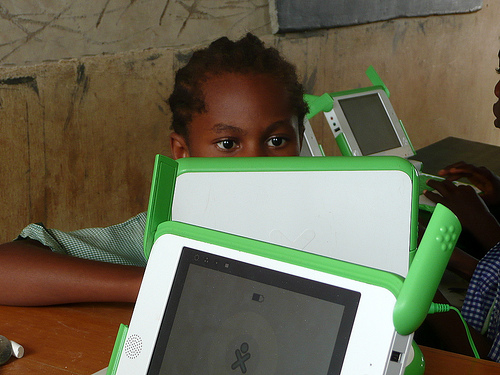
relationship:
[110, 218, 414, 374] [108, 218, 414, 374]
tablet in tablet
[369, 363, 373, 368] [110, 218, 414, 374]
spot on tablet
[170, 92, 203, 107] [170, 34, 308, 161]
braid on head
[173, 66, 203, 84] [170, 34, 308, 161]
braid on head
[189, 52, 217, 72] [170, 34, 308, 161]
braid on head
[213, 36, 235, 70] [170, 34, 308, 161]
braid on head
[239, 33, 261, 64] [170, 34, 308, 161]
braid on head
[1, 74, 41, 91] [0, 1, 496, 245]
dent on wall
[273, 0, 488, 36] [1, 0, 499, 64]
screen on board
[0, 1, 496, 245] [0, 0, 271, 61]
wall with marks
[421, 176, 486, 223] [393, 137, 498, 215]
hand on table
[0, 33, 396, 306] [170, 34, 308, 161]
boy has hair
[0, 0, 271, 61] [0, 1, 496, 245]
scratches on wall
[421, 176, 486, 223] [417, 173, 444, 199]
hand on keyboard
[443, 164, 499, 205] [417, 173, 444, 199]
hand on keyboard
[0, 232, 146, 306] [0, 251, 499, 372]
arm on table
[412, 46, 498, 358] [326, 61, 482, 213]
kid typing on cpu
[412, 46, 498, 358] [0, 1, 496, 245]
kid in background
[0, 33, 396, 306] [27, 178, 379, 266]
kid wearing shirt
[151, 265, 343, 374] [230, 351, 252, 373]
cpu screen with x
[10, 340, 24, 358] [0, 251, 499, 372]
chalk on table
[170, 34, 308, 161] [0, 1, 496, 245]
kids face in view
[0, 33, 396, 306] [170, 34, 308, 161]
person with corn rows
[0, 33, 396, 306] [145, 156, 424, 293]
person looking at monitor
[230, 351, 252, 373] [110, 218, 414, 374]
x on lap top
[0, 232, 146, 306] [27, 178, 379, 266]
arm i shirt